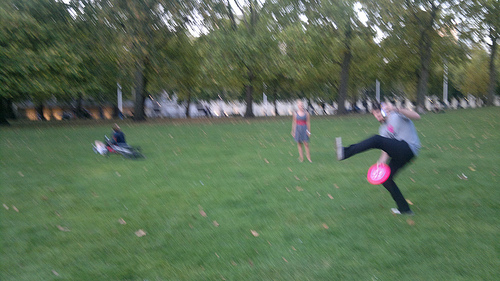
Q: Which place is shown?
A: It is a field.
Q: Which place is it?
A: It is a field.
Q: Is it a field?
A: Yes, it is a field.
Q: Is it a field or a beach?
A: It is a field.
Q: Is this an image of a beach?
A: No, the picture is showing a field.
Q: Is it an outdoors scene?
A: Yes, it is outdoors.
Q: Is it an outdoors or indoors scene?
A: It is outdoors.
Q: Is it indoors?
A: No, it is outdoors.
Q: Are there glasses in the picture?
A: No, there are no glasses.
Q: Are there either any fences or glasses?
A: No, there are no glasses or fences.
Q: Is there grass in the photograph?
A: Yes, there is grass.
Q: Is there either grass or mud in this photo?
A: Yes, there is grass.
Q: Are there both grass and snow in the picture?
A: No, there is grass but no snow.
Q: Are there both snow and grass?
A: No, there is grass but no snow.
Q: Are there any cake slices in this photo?
A: No, there are no cake slices.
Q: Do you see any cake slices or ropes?
A: No, there are no cake slices or ropes.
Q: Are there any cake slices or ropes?
A: No, there are no cake slices or ropes.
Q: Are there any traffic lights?
A: No, there are no traffic lights.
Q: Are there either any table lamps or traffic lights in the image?
A: No, there are no traffic lights or table lamps.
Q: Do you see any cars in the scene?
A: No, there are no cars.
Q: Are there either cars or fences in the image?
A: No, there are no cars or fences.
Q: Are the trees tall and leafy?
A: Yes, the trees are tall and leafy.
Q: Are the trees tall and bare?
A: No, the trees are tall but leafy.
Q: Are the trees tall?
A: Yes, the trees are tall.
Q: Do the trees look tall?
A: Yes, the trees are tall.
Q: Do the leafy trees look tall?
A: Yes, the trees are tall.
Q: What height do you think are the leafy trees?
A: The trees are tall.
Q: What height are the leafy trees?
A: The trees are tall.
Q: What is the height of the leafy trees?
A: The trees are tall.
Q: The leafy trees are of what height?
A: The trees are tall.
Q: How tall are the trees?
A: The trees are tall.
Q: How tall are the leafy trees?
A: The trees are tall.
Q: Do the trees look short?
A: No, the trees are tall.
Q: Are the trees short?
A: No, the trees are tall.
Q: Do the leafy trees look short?
A: No, the trees are tall.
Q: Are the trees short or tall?
A: The trees are tall.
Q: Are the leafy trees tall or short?
A: The trees are tall.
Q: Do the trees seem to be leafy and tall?
A: Yes, the trees are leafy and tall.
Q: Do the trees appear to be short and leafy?
A: No, the trees are leafy but tall.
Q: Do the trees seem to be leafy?
A: Yes, the trees are leafy.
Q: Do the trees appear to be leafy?
A: Yes, the trees are leafy.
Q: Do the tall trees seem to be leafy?
A: Yes, the trees are leafy.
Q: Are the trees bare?
A: No, the trees are leafy.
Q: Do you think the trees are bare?
A: No, the trees are leafy.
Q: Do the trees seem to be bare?
A: No, the trees are leafy.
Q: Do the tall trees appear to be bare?
A: No, the trees are leafy.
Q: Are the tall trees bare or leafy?
A: The trees are leafy.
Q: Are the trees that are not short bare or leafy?
A: The trees are leafy.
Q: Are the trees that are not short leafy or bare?
A: The trees are leafy.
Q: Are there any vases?
A: No, there are no vases.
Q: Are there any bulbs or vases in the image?
A: No, there are no vases or bulbs.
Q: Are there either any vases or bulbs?
A: No, there are no vases or bulbs.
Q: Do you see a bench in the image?
A: No, there are no benches.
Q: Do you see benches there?
A: No, there are no benches.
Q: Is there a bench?
A: No, there are no benches.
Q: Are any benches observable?
A: No, there are no benches.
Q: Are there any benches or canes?
A: No, there are no benches or canes.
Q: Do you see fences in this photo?
A: No, there are no fences.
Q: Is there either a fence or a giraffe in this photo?
A: No, there are no fences or giraffes.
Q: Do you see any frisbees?
A: Yes, there is a frisbee.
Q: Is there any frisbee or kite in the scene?
A: Yes, there is a frisbee.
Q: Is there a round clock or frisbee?
A: Yes, there is a round frisbee.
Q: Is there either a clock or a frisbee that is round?
A: Yes, the frisbee is round.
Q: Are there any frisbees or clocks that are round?
A: Yes, the frisbee is round.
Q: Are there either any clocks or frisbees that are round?
A: Yes, the frisbee is round.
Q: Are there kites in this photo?
A: No, there are no kites.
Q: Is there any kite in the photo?
A: No, there are no kites.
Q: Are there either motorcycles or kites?
A: No, there are no kites or motorcycles.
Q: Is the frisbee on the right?
A: Yes, the frisbee is on the right of the image.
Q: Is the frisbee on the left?
A: No, the frisbee is on the right of the image.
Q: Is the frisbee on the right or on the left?
A: The frisbee is on the right of the image.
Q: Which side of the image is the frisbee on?
A: The frisbee is on the right of the image.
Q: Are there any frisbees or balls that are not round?
A: No, there is a frisbee but it is round.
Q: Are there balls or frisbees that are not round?
A: No, there is a frisbee but it is round.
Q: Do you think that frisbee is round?
A: Yes, the frisbee is round.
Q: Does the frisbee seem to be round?
A: Yes, the frisbee is round.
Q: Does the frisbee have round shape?
A: Yes, the frisbee is round.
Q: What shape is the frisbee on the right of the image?
A: The frisbee is round.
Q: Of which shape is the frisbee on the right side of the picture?
A: The frisbee is round.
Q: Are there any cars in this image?
A: No, there are no cars.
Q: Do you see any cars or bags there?
A: No, there are no cars or bags.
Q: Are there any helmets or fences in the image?
A: No, there are no fences or helmets.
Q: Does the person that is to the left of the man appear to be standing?
A: Yes, the person is standing.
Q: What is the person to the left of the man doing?
A: The person is standing.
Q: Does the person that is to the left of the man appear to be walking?
A: No, the person is standing.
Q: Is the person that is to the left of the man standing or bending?
A: The person is standing.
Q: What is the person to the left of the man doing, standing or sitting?
A: The person is standing.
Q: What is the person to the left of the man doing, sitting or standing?
A: The person is standing.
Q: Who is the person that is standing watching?
A: The person is watching the man.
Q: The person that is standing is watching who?
A: The person is watching the man.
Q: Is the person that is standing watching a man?
A: Yes, the person is watching a man.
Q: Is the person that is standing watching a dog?
A: No, the person is watching a man.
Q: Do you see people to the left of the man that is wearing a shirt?
A: Yes, there is a person to the left of the man.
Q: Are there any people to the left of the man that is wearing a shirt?
A: Yes, there is a person to the left of the man.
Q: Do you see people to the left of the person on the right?
A: Yes, there is a person to the left of the man.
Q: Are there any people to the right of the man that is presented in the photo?
A: No, the person is to the left of the man.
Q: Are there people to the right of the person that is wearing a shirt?
A: No, the person is to the left of the man.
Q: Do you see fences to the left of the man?
A: No, there is a person to the left of the man.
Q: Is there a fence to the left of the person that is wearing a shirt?
A: No, there is a person to the left of the man.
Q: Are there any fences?
A: No, there are no fences.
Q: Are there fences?
A: No, there are no fences.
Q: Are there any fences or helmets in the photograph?
A: No, there are no fences or helmets.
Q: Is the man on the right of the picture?
A: Yes, the man is on the right of the image.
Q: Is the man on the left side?
A: No, the man is on the right of the image.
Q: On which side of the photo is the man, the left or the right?
A: The man is on the right of the image.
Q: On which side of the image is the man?
A: The man is on the right of the image.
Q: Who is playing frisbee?
A: The man is playing frisbee.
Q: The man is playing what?
A: The man is playing frisbee.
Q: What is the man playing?
A: The man is playing frisbee.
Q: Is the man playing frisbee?
A: Yes, the man is playing frisbee.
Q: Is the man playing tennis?
A: No, the man is playing frisbee.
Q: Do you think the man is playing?
A: Yes, the man is playing.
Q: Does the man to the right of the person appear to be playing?
A: Yes, the man is playing.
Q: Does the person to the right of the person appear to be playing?
A: Yes, the man is playing.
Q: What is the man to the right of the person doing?
A: The man is playing.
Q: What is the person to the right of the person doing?
A: The man is playing.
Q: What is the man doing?
A: The man is playing.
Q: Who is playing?
A: The man is playing.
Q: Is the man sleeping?
A: No, the man is playing.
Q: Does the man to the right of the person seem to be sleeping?
A: No, the man is playing.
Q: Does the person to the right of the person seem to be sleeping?
A: No, the man is playing.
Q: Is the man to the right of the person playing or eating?
A: The man is playing.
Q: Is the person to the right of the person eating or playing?
A: The man is playing.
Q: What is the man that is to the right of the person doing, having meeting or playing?
A: The man is playing.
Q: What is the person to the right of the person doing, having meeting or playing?
A: The man is playing.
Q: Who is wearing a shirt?
A: The man is wearing a shirt.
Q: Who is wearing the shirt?
A: The man is wearing a shirt.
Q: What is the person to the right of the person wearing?
A: The man is wearing a shirt.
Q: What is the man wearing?
A: The man is wearing a shirt.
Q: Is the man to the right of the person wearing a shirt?
A: Yes, the man is wearing a shirt.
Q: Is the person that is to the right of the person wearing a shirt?
A: Yes, the man is wearing a shirt.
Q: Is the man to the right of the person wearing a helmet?
A: No, the man is wearing a shirt.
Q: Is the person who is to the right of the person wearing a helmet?
A: No, the man is wearing a shirt.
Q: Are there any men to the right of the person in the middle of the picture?
A: Yes, there is a man to the right of the person.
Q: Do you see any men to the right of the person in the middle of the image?
A: Yes, there is a man to the right of the person.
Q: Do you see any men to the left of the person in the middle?
A: No, the man is to the right of the person.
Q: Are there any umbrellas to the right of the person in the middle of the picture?
A: No, there is a man to the right of the person.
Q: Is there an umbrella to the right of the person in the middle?
A: No, there is a man to the right of the person.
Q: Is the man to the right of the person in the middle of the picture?
A: Yes, the man is to the right of the person.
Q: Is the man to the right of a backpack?
A: No, the man is to the right of the person.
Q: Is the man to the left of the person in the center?
A: No, the man is to the right of the person.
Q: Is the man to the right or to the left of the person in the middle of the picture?
A: The man is to the right of the person.